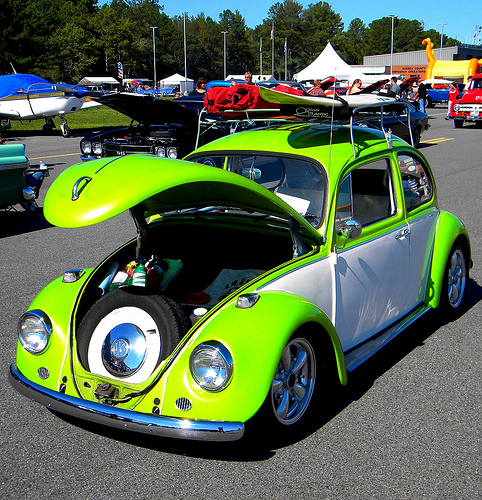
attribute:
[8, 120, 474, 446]
vehicle — green, white, volkswagen, beetle, bright, vw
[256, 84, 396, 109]
surfboard — white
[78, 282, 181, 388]
wheel — spare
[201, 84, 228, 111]
bag — red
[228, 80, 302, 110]
bag — red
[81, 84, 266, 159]
car — black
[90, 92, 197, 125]
hood — up, open, raised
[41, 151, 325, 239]
hood — up, open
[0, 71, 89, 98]
tarp — blue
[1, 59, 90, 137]
plane — white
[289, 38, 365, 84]
tent — white, triangular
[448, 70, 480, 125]
truck — red, vintage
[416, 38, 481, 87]
house — bouncy, yellow, orange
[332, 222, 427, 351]
door — white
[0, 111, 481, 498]
lot — parking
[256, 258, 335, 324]
panel — white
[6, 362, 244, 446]
bumper — chrome